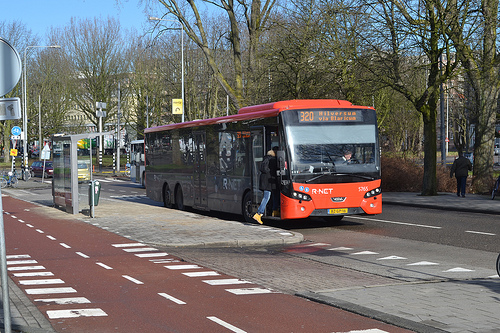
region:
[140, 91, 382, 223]
a silver and orange bus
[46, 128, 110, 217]
an outdoor bus shelter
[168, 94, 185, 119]
a yellow traffic sign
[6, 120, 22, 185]
a blue traffic sign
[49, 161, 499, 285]
a paved city street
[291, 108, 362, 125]
a bus' electronic destination sign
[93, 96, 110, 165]
street name signs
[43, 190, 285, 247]
a brick sidewalk area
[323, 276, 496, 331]
a brick sidewalk area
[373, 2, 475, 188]
a tall green budding tree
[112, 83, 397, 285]
the bus is red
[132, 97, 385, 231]
bus stopped on street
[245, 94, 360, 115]
orange roof on bus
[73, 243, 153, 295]
white lines on red surface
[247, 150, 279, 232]
person boarding bus door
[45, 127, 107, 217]
bus shelter with glass wall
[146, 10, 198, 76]
street light on pole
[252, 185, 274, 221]
leg of blue jeans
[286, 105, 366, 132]
bus number and destination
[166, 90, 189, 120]
yellow sign on pole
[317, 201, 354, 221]
license plate on bus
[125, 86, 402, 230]
bus stopped at the curb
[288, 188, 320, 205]
headlights on a bus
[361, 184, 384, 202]
headlights on a bus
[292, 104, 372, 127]
digital sign on a bus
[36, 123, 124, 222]
metal and glass bus stop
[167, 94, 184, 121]
yellow and black sign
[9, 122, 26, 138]
blue and white sign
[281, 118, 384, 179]
windshield on a bus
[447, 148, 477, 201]
person on the sidewalk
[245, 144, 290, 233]
person getting on the bus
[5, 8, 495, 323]
a local bus in a community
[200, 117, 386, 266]
this passenger is boarding the bus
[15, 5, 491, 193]
it is a fall or spring day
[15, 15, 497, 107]
the trees do not have leaves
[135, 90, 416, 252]
this bus is orange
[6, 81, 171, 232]
there ae a lot of signs and poles in the background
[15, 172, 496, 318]
the street with lots of driving lines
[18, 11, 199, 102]
lampoles over the street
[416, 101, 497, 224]
a man walking through some trees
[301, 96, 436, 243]
a bus driver in the window